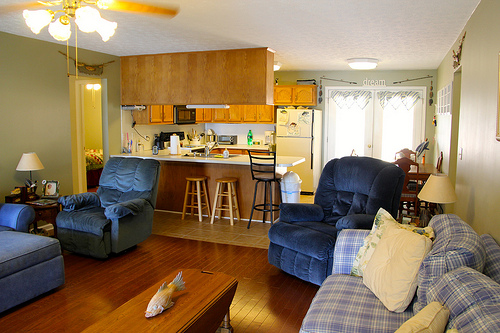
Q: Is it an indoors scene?
A: Yes, it is indoors.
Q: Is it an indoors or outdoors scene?
A: It is indoors.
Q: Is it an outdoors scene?
A: No, it is indoors.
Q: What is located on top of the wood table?
A: The fish is on top of the table.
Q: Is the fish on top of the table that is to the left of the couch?
A: Yes, the fish is on top of the table.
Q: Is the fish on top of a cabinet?
A: No, the fish is on top of the table.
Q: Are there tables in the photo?
A: Yes, there is a table.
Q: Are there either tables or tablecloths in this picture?
A: Yes, there is a table.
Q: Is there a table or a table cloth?
A: Yes, there is a table.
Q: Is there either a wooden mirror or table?
A: Yes, there is a wood table.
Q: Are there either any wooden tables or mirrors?
A: Yes, there is a wood table.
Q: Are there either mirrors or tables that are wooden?
A: Yes, the table is wooden.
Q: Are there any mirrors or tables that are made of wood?
A: Yes, the table is made of wood.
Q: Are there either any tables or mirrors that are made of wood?
A: Yes, the table is made of wood.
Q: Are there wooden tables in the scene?
A: Yes, there is a wood table.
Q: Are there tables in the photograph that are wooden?
A: Yes, there is a table that is wooden.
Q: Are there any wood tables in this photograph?
A: Yes, there is a table that is made of wood.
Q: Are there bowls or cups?
A: No, there are no bowls or cups.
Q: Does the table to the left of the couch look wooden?
A: Yes, the table is wooden.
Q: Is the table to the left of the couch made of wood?
A: Yes, the table is made of wood.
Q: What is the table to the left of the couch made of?
A: The table is made of wood.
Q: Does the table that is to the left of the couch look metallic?
A: No, the table is wooden.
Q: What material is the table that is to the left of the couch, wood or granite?
A: The table is made of wood.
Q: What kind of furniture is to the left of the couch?
A: The piece of furniture is a table.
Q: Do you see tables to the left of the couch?
A: Yes, there is a table to the left of the couch.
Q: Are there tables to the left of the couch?
A: Yes, there is a table to the left of the couch.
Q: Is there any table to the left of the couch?
A: Yes, there is a table to the left of the couch.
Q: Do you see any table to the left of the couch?
A: Yes, there is a table to the left of the couch.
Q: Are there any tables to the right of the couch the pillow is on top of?
A: No, the table is to the left of the couch.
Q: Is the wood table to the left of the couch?
A: Yes, the table is to the left of the couch.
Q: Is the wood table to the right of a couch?
A: No, the table is to the left of a couch.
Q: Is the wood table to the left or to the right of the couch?
A: The table is to the left of the couch.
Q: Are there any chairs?
A: Yes, there is a chair.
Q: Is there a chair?
A: Yes, there is a chair.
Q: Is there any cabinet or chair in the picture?
A: Yes, there is a chair.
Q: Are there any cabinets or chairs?
A: Yes, there is a chair.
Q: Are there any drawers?
A: No, there are no drawers.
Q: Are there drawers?
A: No, there are no drawers.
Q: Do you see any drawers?
A: No, there are no drawers.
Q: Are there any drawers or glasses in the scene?
A: No, there are no drawers or glasses.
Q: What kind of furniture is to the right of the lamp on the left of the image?
A: The piece of furniture is a chair.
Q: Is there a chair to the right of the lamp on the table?
A: Yes, there is a chair to the right of the lamp.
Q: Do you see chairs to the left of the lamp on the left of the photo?
A: No, the chair is to the right of the lamp.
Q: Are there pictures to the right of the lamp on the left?
A: No, there is a chair to the right of the lamp.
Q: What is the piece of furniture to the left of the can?
A: The piece of furniture is a chair.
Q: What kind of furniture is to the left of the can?
A: The piece of furniture is a chair.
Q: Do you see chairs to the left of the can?
A: Yes, there is a chair to the left of the can.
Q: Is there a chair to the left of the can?
A: Yes, there is a chair to the left of the can.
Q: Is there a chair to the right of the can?
A: No, the chair is to the left of the can.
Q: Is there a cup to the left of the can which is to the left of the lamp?
A: No, there is a chair to the left of the can.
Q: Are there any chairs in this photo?
A: Yes, there is a chair.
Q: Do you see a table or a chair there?
A: Yes, there is a chair.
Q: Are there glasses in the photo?
A: No, there are no glasses.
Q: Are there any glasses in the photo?
A: No, there are no glasses.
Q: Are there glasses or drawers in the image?
A: No, there are no glasses or drawers.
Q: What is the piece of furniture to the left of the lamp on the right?
A: The piece of furniture is a chair.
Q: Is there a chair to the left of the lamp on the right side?
A: Yes, there is a chair to the left of the lamp.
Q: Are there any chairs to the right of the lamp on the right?
A: No, the chair is to the left of the lamp.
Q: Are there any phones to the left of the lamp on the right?
A: No, there is a chair to the left of the lamp.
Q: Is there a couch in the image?
A: Yes, there is a couch.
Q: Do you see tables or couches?
A: Yes, there is a couch.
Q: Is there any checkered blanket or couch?
A: Yes, there is a checkered couch.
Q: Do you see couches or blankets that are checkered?
A: Yes, the couch is checkered.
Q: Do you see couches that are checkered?
A: Yes, there is a checkered couch.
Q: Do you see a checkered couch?
A: Yes, there is a checkered couch.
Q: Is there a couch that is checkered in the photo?
A: Yes, there is a checkered couch.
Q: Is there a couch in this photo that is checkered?
A: Yes, there is a couch that is checkered.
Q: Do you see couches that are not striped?
A: Yes, there is a checkered couch.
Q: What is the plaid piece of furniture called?
A: The piece of furniture is a couch.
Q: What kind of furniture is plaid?
A: The furniture is a couch.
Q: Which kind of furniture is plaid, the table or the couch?
A: The couch is plaid.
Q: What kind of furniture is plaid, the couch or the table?
A: The couch is plaid.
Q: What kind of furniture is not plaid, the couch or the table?
A: The table is not plaid.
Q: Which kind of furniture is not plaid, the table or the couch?
A: The table is not plaid.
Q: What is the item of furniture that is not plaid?
A: The piece of furniture is a table.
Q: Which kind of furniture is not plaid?
A: The furniture is a table.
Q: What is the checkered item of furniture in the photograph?
A: The piece of furniture is a couch.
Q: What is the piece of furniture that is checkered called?
A: The piece of furniture is a couch.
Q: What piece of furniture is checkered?
A: The piece of furniture is a couch.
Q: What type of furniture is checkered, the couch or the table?
A: The couch is checkered.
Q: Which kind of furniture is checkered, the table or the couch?
A: The couch is checkered.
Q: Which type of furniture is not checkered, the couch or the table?
A: The table is not checkered.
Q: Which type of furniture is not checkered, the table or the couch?
A: The table is not checkered.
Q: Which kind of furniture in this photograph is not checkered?
A: The furniture is a table.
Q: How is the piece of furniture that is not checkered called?
A: The piece of furniture is a table.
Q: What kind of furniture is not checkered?
A: The furniture is a table.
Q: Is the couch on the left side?
A: No, the couch is on the right of the image.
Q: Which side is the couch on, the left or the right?
A: The couch is on the right of the image.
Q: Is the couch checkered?
A: Yes, the couch is checkered.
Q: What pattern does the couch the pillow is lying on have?
A: The couch has checkered pattern.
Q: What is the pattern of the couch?
A: The couch is checkered.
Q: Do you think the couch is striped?
A: No, the couch is checkered.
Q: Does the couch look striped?
A: No, the couch is checkered.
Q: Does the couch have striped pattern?
A: No, the couch is checkered.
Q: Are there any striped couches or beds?
A: No, there is a couch but it is checkered.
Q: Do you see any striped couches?
A: No, there is a couch but it is checkered.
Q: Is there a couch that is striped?
A: No, there is a couch but it is checkered.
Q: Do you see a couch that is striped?
A: No, there is a couch but it is checkered.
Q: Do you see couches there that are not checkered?
A: No, there is a couch but it is checkered.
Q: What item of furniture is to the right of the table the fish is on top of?
A: The piece of furniture is a couch.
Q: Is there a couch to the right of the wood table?
A: Yes, there is a couch to the right of the table.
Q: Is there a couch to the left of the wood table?
A: No, the couch is to the right of the table.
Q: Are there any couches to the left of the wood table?
A: No, the couch is to the right of the table.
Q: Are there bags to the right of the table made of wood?
A: No, there is a couch to the right of the table.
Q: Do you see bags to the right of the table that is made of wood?
A: No, there is a couch to the right of the table.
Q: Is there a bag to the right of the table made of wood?
A: No, there is a couch to the right of the table.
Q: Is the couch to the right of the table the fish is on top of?
A: Yes, the couch is to the right of the table.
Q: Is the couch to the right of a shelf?
A: No, the couch is to the right of the table.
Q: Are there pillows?
A: Yes, there is a pillow.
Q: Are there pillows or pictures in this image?
A: Yes, there is a pillow.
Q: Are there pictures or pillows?
A: Yes, there is a pillow.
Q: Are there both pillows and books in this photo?
A: No, there is a pillow but no books.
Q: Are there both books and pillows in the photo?
A: No, there is a pillow but no books.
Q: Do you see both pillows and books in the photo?
A: No, there is a pillow but no books.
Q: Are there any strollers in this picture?
A: No, there are no strollers.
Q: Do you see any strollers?
A: No, there are no strollers.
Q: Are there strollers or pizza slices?
A: No, there are no strollers or pizza slices.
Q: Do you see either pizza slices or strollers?
A: No, there are no strollers or pizza slices.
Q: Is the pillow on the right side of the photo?
A: Yes, the pillow is on the right of the image.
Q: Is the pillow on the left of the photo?
A: No, the pillow is on the right of the image.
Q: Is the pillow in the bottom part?
A: Yes, the pillow is in the bottom of the image.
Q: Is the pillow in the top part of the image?
A: No, the pillow is in the bottom of the image.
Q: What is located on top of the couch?
A: The pillow is on top of the couch.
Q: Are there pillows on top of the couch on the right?
A: Yes, there is a pillow on top of the couch.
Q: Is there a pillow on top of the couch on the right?
A: Yes, there is a pillow on top of the couch.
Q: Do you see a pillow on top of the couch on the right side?
A: Yes, there is a pillow on top of the couch.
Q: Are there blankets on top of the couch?
A: No, there is a pillow on top of the couch.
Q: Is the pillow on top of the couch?
A: Yes, the pillow is on top of the couch.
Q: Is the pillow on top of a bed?
A: No, the pillow is on top of the couch.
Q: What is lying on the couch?
A: The pillow is lying on the couch.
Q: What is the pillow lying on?
A: The pillow is lying on the couch.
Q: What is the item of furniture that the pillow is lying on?
A: The piece of furniture is a couch.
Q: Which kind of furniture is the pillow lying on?
A: The pillow is lying on the couch.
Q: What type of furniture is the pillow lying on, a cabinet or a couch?
A: The pillow is lying on a couch.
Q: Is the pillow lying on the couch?
A: Yes, the pillow is lying on the couch.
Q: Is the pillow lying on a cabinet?
A: No, the pillow is lying on the couch.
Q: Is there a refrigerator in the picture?
A: Yes, there is a refrigerator.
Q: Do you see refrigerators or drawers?
A: Yes, there is a refrigerator.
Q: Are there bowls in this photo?
A: No, there are no bowls.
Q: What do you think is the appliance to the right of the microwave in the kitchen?
A: The appliance is a refrigerator.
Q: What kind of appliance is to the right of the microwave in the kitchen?
A: The appliance is a refrigerator.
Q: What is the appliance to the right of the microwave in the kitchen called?
A: The appliance is a refrigerator.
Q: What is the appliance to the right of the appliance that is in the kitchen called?
A: The appliance is a refrigerator.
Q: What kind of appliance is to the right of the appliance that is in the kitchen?
A: The appliance is a refrigerator.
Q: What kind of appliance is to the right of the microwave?
A: The appliance is a refrigerator.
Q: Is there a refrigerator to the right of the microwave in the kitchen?
A: Yes, there is a refrigerator to the right of the microwave.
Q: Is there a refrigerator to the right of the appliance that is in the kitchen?
A: Yes, there is a refrigerator to the right of the microwave.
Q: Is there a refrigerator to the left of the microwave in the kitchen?
A: No, the refrigerator is to the right of the microwave.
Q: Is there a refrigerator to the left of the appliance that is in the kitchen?
A: No, the refrigerator is to the right of the microwave.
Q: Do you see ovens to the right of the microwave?
A: No, there is a refrigerator to the right of the microwave.